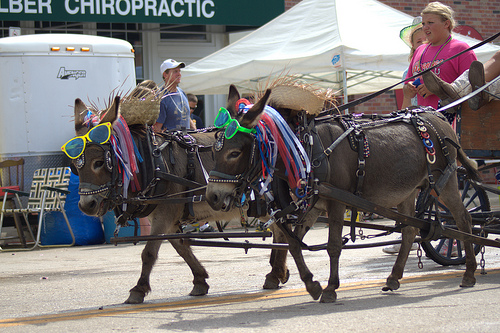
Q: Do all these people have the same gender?
A: No, they are both male and female.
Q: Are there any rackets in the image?
A: No, there are no rackets.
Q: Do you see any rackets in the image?
A: No, there are no rackets.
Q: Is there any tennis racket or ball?
A: No, there are no rackets or balls.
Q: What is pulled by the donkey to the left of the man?
A: The cart is pulled by the donkey.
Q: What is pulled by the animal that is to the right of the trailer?
A: The cart is pulled by the donkey.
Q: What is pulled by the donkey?
A: The cart is pulled by the donkey.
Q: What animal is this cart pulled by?
A: The cart is pulled by the donkey.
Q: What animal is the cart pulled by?
A: The cart is pulled by the donkey.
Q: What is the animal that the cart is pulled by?
A: The animal is a donkey.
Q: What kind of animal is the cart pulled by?
A: The cart is pulled by the donkey.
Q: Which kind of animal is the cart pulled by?
A: The cart is pulled by the donkey.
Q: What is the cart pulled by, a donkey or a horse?
A: The cart is pulled by a donkey.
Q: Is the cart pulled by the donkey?
A: Yes, the cart is pulled by the donkey.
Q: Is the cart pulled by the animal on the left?
A: Yes, the cart is pulled by the donkey.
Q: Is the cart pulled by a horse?
A: No, the cart is pulled by the donkey.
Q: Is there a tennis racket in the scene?
A: No, there are no rackets.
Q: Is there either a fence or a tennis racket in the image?
A: No, there are no rackets or fences.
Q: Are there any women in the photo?
A: Yes, there is a woman.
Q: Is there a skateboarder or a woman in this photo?
A: Yes, there is a woman.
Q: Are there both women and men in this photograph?
A: Yes, there are both a woman and a man.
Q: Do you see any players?
A: No, there are no players.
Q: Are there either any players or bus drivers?
A: No, there are no players or bus drivers.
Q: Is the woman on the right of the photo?
A: Yes, the woman is on the right of the image.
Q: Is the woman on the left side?
A: No, the woman is on the right of the image.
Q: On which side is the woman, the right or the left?
A: The woman is on the right of the image.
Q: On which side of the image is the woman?
A: The woman is on the right of the image.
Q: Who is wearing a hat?
A: The woman is wearing a hat.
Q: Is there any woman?
A: Yes, there is a woman.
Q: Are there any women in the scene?
A: Yes, there is a woman.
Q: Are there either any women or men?
A: Yes, there is a woman.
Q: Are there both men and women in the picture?
A: Yes, there are both a woman and a man.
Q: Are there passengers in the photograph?
A: No, there are no passengers.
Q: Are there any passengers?
A: No, there are no passengers.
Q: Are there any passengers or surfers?
A: No, there are no passengers or surfers.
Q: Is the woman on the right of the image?
A: Yes, the woman is on the right of the image.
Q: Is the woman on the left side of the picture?
A: No, the woman is on the right of the image.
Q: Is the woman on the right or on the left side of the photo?
A: The woman is on the right of the image.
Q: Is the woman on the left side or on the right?
A: The woman is on the right of the image.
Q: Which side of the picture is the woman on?
A: The woman is on the right of the image.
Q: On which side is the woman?
A: The woman is on the right of the image.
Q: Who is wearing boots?
A: The woman is wearing boots.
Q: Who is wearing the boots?
A: The woman is wearing boots.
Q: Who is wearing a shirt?
A: The woman is wearing a shirt.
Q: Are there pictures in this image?
A: No, there are no pictures.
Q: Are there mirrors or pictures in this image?
A: No, there are no pictures or mirrors.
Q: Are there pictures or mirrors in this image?
A: No, there are no pictures or mirrors.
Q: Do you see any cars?
A: No, there are no cars.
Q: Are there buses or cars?
A: No, there are no cars or buses.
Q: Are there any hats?
A: Yes, there is a hat.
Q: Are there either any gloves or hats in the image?
A: Yes, there is a hat.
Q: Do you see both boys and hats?
A: No, there is a hat but no boys.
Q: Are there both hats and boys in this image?
A: No, there is a hat but no boys.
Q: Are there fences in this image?
A: No, there are no fences.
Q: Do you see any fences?
A: No, there are no fences.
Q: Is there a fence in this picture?
A: No, there are no fences.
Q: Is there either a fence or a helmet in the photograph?
A: No, there are no fences or helmets.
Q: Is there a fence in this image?
A: No, there are no fences.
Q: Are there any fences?
A: No, there are no fences.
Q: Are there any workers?
A: No, there are no workers.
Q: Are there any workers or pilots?
A: No, there are no workers or pilots.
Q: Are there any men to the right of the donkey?
A: Yes, there is a man to the right of the donkey.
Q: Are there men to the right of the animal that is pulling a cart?
A: Yes, there is a man to the right of the donkey.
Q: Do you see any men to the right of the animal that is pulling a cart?
A: Yes, there is a man to the right of the donkey.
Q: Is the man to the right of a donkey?
A: Yes, the man is to the right of a donkey.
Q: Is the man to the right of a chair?
A: No, the man is to the right of a donkey.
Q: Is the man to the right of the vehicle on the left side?
A: Yes, the man is to the right of the trailer.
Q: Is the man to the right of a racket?
A: No, the man is to the right of the trailer.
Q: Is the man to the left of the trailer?
A: No, the man is to the right of the trailer.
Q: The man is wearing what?
A: The man is wearing a hat.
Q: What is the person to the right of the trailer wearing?
A: The man is wearing a hat.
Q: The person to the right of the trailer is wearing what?
A: The man is wearing a hat.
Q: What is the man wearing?
A: The man is wearing a hat.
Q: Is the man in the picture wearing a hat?
A: Yes, the man is wearing a hat.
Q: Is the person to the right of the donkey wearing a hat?
A: Yes, the man is wearing a hat.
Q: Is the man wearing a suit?
A: No, the man is wearing a hat.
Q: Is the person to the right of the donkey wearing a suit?
A: No, the man is wearing a hat.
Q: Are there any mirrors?
A: No, there are no mirrors.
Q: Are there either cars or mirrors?
A: No, there are no mirrors or cars.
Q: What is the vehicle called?
A: The vehicle is a trailer.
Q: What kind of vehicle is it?
A: The vehicle is a trailer.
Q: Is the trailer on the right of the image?
A: No, the trailer is on the left of the image.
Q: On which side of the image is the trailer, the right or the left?
A: The trailer is on the left of the image.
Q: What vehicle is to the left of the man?
A: The vehicle is a trailer.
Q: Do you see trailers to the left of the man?
A: Yes, there is a trailer to the left of the man.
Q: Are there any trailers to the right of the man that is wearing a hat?
A: No, the trailer is to the left of the man.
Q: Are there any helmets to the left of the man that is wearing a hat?
A: No, there is a trailer to the left of the man.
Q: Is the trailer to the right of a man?
A: No, the trailer is to the left of a man.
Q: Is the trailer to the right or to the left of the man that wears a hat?
A: The trailer is to the left of the man.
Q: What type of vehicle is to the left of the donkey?
A: The vehicle is a trailer.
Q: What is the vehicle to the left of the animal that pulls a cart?
A: The vehicle is a trailer.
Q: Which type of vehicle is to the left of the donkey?
A: The vehicle is a trailer.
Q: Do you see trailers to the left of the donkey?
A: Yes, there is a trailer to the left of the donkey.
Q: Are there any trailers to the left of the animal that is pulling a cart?
A: Yes, there is a trailer to the left of the donkey.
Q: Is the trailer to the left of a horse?
A: No, the trailer is to the left of a donkey.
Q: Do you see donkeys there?
A: Yes, there is a donkey.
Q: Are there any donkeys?
A: Yes, there is a donkey.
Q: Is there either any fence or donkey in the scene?
A: Yes, there is a donkey.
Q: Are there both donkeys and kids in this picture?
A: No, there is a donkey but no children.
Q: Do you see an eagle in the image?
A: No, there are no eagles.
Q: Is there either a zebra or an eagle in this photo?
A: No, there are no eagles or zebras.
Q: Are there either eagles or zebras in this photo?
A: No, there are no eagles or zebras.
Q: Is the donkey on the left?
A: Yes, the donkey is on the left of the image.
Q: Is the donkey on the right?
A: No, the donkey is on the left of the image.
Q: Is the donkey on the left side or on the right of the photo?
A: The donkey is on the left of the image.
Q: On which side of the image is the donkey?
A: The donkey is on the left of the image.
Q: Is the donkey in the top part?
A: Yes, the donkey is in the top of the image.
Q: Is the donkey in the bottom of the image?
A: No, the donkey is in the top of the image.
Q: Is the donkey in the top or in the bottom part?
A: The donkey is in the top of the image.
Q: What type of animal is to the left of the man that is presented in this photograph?
A: The animal is a donkey.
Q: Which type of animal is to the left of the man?
A: The animal is a donkey.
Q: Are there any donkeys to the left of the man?
A: Yes, there is a donkey to the left of the man.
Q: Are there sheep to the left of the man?
A: No, there is a donkey to the left of the man.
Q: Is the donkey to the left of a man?
A: Yes, the donkey is to the left of a man.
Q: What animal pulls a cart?
A: The donkey pulls a cart.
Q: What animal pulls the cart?
A: The donkey pulls a cart.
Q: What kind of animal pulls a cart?
A: The animal is a donkey.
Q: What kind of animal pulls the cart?
A: The animal is a donkey.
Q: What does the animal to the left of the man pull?
A: The donkey pulls a cart.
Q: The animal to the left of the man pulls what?
A: The donkey pulls a cart.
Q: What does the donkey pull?
A: The donkey pulls a cart.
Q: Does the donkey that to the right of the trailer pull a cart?
A: Yes, the donkey pulls a cart.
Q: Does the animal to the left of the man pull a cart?
A: Yes, the donkey pulls a cart.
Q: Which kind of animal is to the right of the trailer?
A: The animal is a donkey.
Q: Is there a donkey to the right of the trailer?
A: Yes, there is a donkey to the right of the trailer.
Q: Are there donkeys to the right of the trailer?
A: Yes, there is a donkey to the right of the trailer.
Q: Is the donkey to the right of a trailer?
A: Yes, the donkey is to the right of a trailer.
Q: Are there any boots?
A: Yes, there are boots.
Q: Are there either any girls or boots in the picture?
A: Yes, there are boots.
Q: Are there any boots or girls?
A: Yes, there are boots.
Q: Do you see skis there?
A: No, there are no skis.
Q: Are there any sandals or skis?
A: No, there are no skis or sandals.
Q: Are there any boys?
A: No, there are no boys.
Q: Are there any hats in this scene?
A: Yes, there is a hat.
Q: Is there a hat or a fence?
A: Yes, there is a hat.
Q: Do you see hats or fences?
A: Yes, there is a hat.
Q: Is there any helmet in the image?
A: No, there are no helmets.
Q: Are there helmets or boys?
A: No, there are no helmets or boys.